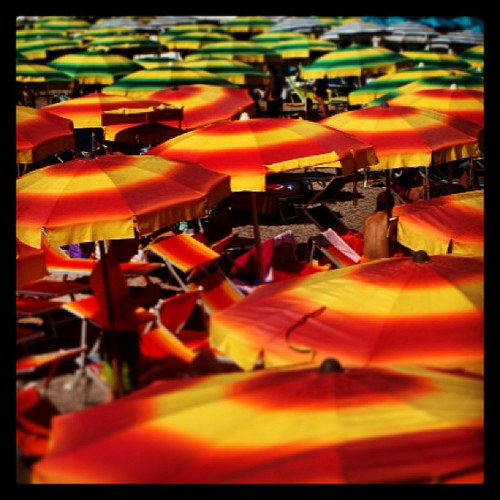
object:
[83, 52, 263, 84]
green/yellow stripes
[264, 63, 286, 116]
person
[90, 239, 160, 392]
man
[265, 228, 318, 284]
chair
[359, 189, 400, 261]
man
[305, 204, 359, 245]
chairs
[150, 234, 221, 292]
seat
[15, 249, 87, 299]
seat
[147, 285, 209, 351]
seat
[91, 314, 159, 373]
seat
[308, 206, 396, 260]
seat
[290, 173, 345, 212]
chair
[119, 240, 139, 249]
glasses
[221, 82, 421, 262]
sand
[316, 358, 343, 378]
tip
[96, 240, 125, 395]
unbrella pole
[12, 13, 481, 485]
umbrella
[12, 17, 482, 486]
beach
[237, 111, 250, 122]
tip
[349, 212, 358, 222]
footprints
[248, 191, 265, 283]
pole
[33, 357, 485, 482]
top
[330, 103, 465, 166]
top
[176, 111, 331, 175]
top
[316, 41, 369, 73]
top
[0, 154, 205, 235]
top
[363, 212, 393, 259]
back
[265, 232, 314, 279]
towel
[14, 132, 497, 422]
ground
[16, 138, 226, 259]
umbrella